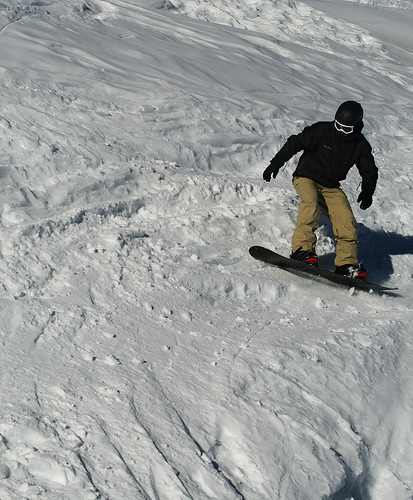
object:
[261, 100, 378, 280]
man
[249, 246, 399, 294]
snowboard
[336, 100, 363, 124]
hat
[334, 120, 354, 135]
goggles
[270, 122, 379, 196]
coat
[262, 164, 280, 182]
glove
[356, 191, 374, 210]
glove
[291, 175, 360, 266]
pants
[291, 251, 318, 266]
shoe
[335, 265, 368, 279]
shoe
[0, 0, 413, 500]
hill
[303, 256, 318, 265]
bottom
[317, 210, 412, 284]
shadow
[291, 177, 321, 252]
leg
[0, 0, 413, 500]
snow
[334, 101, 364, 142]
head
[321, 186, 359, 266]
leg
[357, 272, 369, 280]
bottom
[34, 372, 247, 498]
tracks